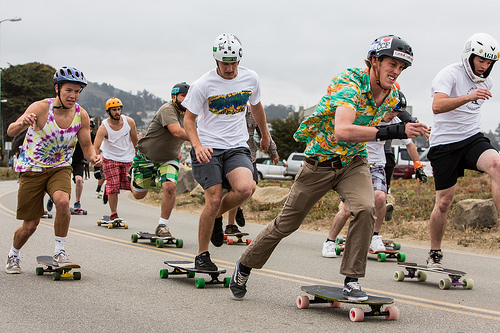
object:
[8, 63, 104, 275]
man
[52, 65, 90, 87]
helmet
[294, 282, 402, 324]
skateboard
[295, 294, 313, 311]
wheel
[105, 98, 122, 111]
helmet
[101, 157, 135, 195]
shorts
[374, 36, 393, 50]
sticker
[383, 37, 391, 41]
heart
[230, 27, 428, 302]
man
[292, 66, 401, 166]
shirt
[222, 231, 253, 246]
skateboard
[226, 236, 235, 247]
wheel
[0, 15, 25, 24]
streetlight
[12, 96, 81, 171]
tank top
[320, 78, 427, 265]
man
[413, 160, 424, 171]
orange band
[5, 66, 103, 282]
guys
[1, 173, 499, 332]
road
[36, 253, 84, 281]
skateboards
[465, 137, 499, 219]
leg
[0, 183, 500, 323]
stripes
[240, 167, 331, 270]
leg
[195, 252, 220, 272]
foot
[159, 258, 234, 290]
skateboard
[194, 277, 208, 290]
wheel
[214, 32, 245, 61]
helmet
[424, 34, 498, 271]
man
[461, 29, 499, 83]
helmet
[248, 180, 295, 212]
rock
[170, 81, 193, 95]
helmet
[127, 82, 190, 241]
man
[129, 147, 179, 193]
shorts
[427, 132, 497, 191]
shorts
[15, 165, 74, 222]
shorts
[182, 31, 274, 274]
man